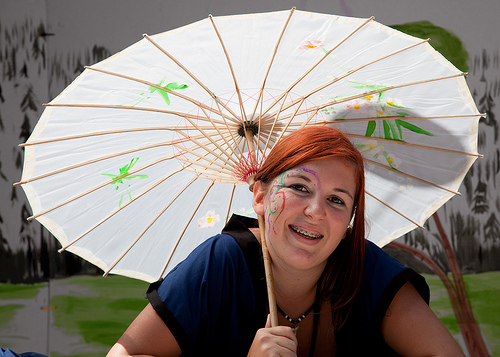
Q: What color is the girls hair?
A: Red.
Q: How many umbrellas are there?
A: One.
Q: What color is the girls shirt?
A: Blue.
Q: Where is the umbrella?
A: Behind the girls head.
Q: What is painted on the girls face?
A: Decoration.